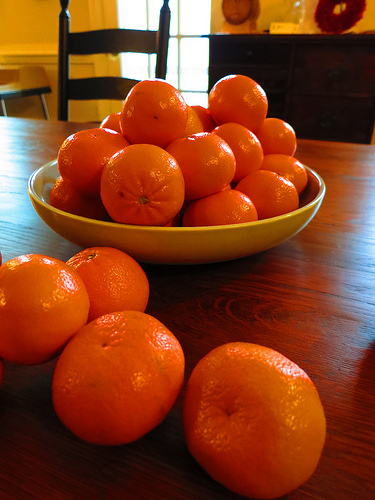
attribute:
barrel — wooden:
[217, 0, 267, 31]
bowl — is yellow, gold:
[28, 151, 330, 267]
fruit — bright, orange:
[98, 140, 185, 224]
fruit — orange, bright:
[181, 188, 258, 229]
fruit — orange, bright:
[233, 169, 300, 219]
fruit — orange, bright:
[207, 71, 269, 129]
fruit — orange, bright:
[56, 127, 131, 195]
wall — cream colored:
[2, 4, 53, 42]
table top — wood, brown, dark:
[282, 252, 361, 303]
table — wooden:
[1, 137, 373, 498]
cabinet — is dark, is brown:
[227, 22, 373, 138]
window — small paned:
[116, 0, 210, 107]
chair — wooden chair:
[0, 113, 372, 498]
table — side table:
[0, 67, 53, 115]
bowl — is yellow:
[13, 154, 334, 280]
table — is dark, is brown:
[4, 105, 373, 433]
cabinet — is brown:
[209, 23, 374, 144]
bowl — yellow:
[34, 175, 335, 247]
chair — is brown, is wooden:
[46, 15, 204, 68]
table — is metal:
[2, 82, 52, 117]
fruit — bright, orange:
[202, 70, 272, 138]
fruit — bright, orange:
[178, 339, 334, 499]